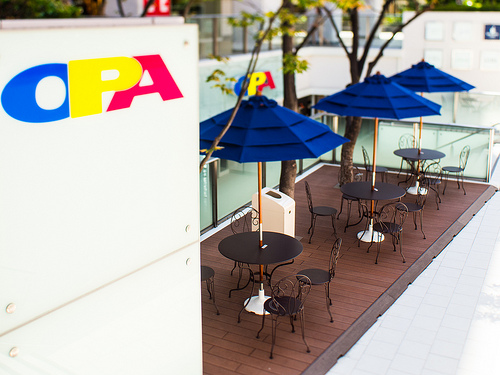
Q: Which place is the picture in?
A: It is at the patio.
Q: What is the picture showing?
A: It is showing a patio.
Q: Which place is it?
A: It is a patio.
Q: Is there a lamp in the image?
A: No, there are no lamps.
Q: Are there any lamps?
A: No, there are no lamps.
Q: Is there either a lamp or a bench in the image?
A: No, there are no lamps or benches.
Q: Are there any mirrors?
A: No, there are no mirrors.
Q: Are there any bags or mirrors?
A: No, there are no mirrors or bags.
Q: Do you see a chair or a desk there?
A: Yes, there is a chair.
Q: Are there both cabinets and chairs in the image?
A: No, there is a chair but no cabinets.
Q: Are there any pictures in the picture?
A: No, there are no pictures.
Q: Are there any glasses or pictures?
A: No, there are no pictures or glasses.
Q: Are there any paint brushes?
A: No, there are no paint brushes.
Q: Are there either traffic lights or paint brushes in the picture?
A: No, there are no paint brushes or traffic lights.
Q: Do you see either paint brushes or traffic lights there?
A: No, there are no paint brushes or traffic lights.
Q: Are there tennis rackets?
A: No, there are no tennis rackets.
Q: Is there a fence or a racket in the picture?
A: No, there are no rackets or fences.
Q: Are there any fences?
A: No, there are no fences.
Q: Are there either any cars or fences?
A: No, there are no fences or cars.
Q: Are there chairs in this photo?
A: Yes, there is a chair.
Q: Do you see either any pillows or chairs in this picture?
A: Yes, there is a chair.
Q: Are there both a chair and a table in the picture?
A: Yes, there are both a chair and a table.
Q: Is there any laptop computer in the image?
A: No, there are no laptops.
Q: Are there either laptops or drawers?
A: No, there are no laptops or drawers.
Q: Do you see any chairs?
A: Yes, there is a chair.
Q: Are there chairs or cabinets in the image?
A: Yes, there is a chair.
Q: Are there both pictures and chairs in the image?
A: No, there is a chair but no pictures.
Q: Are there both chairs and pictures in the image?
A: No, there is a chair but no pictures.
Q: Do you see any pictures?
A: No, there are no pictures.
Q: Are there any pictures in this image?
A: No, there are no pictures.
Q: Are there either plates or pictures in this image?
A: No, there are no pictures or plates.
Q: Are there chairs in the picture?
A: Yes, there is a chair.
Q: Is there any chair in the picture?
A: Yes, there is a chair.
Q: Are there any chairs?
A: Yes, there is a chair.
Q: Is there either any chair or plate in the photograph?
A: Yes, there is a chair.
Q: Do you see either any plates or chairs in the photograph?
A: Yes, there is a chair.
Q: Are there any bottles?
A: No, there are no bottles.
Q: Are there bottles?
A: No, there are no bottles.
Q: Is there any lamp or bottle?
A: No, there are no bottles or lamps.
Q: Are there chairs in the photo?
A: Yes, there is a chair.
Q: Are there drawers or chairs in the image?
A: Yes, there is a chair.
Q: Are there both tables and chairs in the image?
A: Yes, there are both a chair and a table.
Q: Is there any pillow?
A: No, there are no pillows.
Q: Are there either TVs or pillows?
A: No, there are no pillows or tvs.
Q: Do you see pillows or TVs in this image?
A: No, there are no pillows or tvs.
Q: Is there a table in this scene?
A: Yes, there is a table.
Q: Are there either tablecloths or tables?
A: Yes, there is a table.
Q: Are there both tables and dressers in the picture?
A: No, there is a table but no dressers.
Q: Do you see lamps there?
A: No, there are no lamps.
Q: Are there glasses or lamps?
A: No, there are no lamps or glasses.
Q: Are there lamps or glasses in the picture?
A: No, there are no lamps or glasses.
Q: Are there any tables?
A: Yes, there is a table.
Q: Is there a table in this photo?
A: Yes, there is a table.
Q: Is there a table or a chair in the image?
A: Yes, there is a table.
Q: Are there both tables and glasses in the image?
A: No, there is a table but no glasses.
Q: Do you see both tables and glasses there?
A: No, there is a table but no glasses.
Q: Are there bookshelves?
A: No, there are no bookshelves.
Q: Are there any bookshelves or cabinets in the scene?
A: No, there are no bookshelves or cabinets.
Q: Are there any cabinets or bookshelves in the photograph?
A: No, there are no bookshelves or cabinets.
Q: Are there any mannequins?
A: No, there are no mannequins.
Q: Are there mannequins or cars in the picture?
A: No, there are no mannequins or cars.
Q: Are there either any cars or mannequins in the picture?
A: No, there are no mannequins or cars.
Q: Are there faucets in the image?
A: No, there are no faucets.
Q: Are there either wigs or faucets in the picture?
A: No, there are no faucets or wigs.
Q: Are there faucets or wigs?
A: No, there are no faucets or wigs.